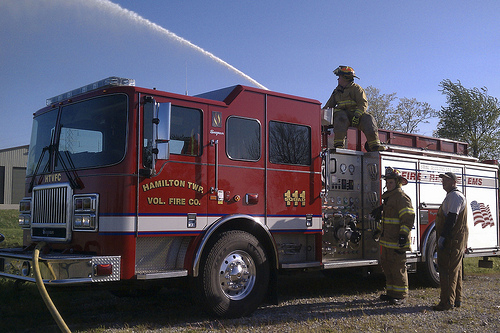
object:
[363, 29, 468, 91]
sky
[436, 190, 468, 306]
pants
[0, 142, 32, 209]
building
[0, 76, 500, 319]
firetruck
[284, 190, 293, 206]
numbers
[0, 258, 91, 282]
surface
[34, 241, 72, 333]
pipe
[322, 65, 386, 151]
firefighter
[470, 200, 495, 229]
flag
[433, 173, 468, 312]
firefighters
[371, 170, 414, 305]
firefighter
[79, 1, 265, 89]
water